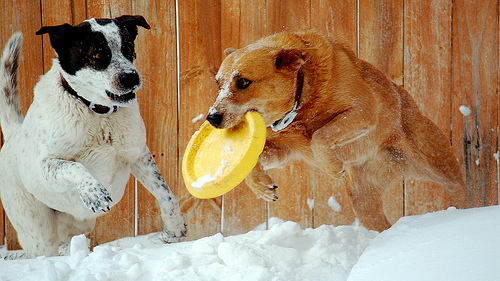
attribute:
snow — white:
[211, 239, 496, 279]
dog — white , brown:
[196, 27, 498, 234]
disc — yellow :
[183, 110, 267, 198]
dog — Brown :
[189, 43, 426, 204]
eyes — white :
[83, 39, 141, 67]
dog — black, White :
[0, 18, 169, 272]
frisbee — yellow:
[180, 110, 265, 199]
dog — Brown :
[206, 29, 471, 216]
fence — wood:
[3, 1, 498, 212]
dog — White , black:
[2, 11, 185, 253]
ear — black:
[33, 22, 69, 46]